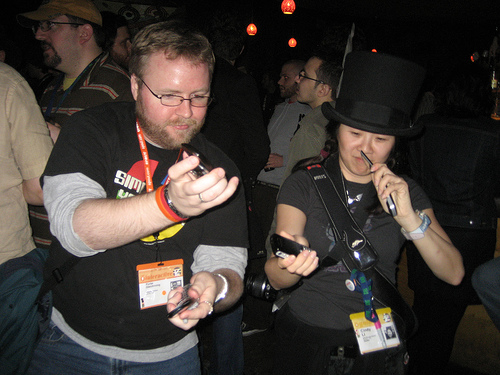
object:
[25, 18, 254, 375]
man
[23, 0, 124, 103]
man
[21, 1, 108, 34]
cap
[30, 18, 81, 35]
glasses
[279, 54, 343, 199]
man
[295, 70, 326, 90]
glasses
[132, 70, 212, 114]
glasses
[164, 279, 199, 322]
phone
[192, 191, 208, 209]
ring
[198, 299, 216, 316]
ring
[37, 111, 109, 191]
sleeve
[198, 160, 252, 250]
sleeve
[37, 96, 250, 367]
shirt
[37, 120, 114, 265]
sleeve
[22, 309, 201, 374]
jeans